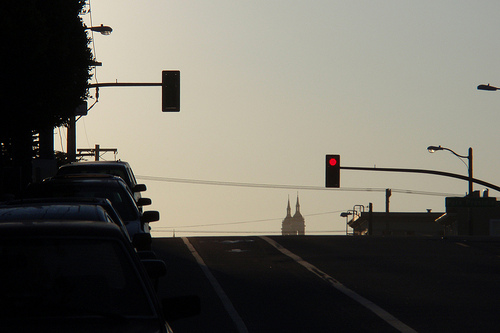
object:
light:
[329, 158, 337, 166]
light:
[91, 26, 113, 36]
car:
[0, 220, 173, 332]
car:
[16, 172, 161, 239]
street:
[0, 232, 500, 333]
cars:
[0, 160, 172, 332]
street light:
[162, 70, 180, 112]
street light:
[426, 145, 440, 153]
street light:
[477, 84, 497, 91]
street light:
[325, 154, 340, 189]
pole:
[338, 167, 500, 192]